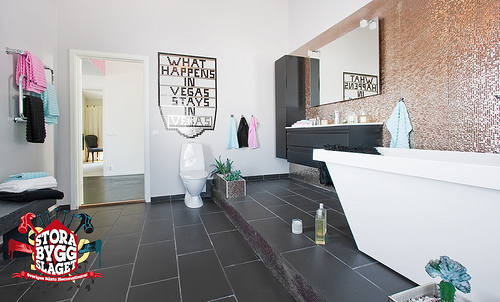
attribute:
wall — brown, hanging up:
[296, 32, 500, 144]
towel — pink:
[21, 49, 42, 91]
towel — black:
[26, 98, 43, 139]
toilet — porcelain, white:
[181, 145, 207, 204]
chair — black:
[86, 133, 102, 155]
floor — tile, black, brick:
[26, 192, 368, 300]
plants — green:
[203, 156, 252, 194]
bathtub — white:
[316, 139, 500, 281]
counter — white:
[285, 115, 381, 129]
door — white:
[82, 57, 145, 187]